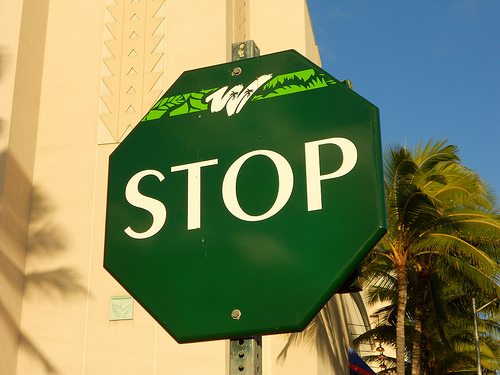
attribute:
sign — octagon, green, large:
[102, 48, 388, 345]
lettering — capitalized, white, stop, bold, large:
[122, 136, 358, 241]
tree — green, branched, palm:
[363, 135, 500, 374]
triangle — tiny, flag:
[345, 345, 376, 373]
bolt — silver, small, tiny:
[229, 309, 243, 319]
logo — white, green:
[141, 64, 337, 123]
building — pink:
[1, 0, 405, 374]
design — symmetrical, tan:
[96, 1, 170, 145]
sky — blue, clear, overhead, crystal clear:
[307, 0, 498, 343]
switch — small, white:
[107, 293, 134, 322]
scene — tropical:
[1, 3, 500, 373]